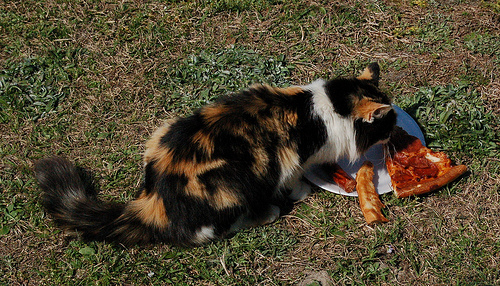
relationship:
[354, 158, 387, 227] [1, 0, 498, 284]
pizza crust touching grass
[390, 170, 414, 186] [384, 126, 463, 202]
pepperoni on top of pizza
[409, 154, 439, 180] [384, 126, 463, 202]
pepperoni on top of pizza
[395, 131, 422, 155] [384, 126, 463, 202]
pepperoni on top of pizza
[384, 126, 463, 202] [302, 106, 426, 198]
pizza on top of plate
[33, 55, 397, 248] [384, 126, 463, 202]
cat eating pizza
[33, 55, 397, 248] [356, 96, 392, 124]
cat has ear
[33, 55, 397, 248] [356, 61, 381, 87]
cat has ear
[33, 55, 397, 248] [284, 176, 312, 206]
cat has paw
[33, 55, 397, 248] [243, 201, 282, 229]
cat has paw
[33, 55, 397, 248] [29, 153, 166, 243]
cat has tail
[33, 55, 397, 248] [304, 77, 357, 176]
cat has neck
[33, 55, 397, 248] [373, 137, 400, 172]
cat has whiskers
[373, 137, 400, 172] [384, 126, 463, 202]
whiskers are touching pizza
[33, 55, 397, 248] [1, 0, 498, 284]
cat sitting on grass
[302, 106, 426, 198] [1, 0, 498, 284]
plate sitting on top of grass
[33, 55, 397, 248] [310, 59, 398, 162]
cat has head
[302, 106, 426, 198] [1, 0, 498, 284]
plate set on grass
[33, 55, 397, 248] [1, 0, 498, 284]
cat perched on grass